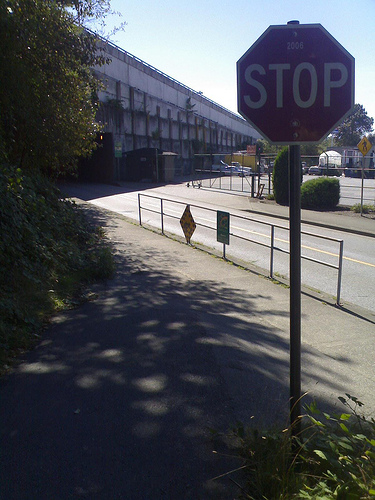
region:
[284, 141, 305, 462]
black metal pole supporting sign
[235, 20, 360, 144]
red and white octagonal sign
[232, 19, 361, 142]
red sign meaning STOP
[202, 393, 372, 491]
green grass and undergrowth in foreground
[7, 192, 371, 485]
grey concrete path near sign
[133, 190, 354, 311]
metal guard rail on street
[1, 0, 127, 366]
fluffy bushy green trees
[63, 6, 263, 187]
white stone bridge in background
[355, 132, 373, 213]
yellow and black walk sign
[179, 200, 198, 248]
yellow triangular street sign on metal fence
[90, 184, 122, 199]
this is the road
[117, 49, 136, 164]
this is a bridge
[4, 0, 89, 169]
these are some trees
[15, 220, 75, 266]
this is the grass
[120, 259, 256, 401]
shadow of the trees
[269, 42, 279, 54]
the signboard is red in color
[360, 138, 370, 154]
the signboard is yellow in color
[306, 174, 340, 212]
this is a hedge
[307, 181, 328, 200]
the hedge leaves are green in color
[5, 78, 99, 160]
part of a tree's branch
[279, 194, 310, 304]
part of a metal post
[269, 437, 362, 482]
leaves of a plant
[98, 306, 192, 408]
part of a walking path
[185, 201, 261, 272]
part of a metal fence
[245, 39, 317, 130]
a red stop sign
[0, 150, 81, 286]
part of a bushy bush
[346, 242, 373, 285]
section of the road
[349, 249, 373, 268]
yellow line on the road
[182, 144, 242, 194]
part of a meshed gate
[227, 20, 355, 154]
a red traffic sign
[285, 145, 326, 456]
a metal pole supporting a sign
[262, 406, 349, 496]
a green plant growing around the sign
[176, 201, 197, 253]
a yellow road sign on the gate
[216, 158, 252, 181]
cars parked in a lot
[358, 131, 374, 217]
yellow pedestrian sign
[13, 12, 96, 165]
a tree growing on the hill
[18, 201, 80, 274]
rocks scattered in the grass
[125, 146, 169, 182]
a dumpster outside a building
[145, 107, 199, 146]
pipes running down the wall of a building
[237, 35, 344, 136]
this is a stop sign post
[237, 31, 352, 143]
the stop sign is red in color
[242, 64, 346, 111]
the stop is written in bold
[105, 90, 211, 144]
this is a building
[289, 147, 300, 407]
this pole is straight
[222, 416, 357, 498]
grass are down the post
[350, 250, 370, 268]
yellow strip is on the road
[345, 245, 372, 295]
the road is clear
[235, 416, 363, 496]
the grass are green in color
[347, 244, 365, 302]
the road is clean